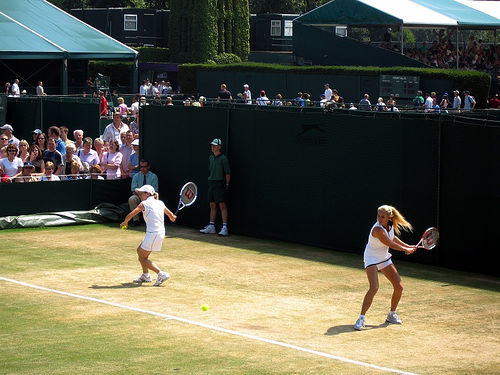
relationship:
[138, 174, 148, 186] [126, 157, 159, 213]
tie around man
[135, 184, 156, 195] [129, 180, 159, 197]
cap on head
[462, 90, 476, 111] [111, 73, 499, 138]
person in stands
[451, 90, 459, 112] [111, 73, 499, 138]
person in stands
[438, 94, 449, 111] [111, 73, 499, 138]
person in stands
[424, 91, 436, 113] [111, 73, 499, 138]
person in stands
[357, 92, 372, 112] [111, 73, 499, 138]
person in stands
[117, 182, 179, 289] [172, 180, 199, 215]
woman holding racket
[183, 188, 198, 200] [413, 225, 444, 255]
red logo on racket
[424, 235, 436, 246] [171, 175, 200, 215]
red logo on racket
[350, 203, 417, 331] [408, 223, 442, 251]
girl holding tennis racquet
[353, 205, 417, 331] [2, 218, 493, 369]
girl on court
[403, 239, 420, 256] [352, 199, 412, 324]
hand on woman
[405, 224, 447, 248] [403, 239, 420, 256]
racket in hand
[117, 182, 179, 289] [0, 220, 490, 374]
woman on court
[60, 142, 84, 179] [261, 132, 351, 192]
spectator behind fence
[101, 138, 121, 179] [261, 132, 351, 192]
spectator behind fence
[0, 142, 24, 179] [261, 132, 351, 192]
spectator behind fence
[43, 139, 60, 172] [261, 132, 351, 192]
spectator behind fence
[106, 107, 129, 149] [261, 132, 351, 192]
spectator behind fence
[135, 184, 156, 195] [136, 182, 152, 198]
cap on head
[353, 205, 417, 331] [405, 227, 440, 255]
girl holding racket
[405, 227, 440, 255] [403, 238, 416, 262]
racket with both hands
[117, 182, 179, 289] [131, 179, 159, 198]
woman wearing cap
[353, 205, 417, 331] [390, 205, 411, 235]
girl with ponytail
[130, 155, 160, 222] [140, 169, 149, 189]
man wearing tie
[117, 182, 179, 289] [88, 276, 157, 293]
woman casting shadow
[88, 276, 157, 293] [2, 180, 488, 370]
shadow cast on court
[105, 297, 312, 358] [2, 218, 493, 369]
line on court